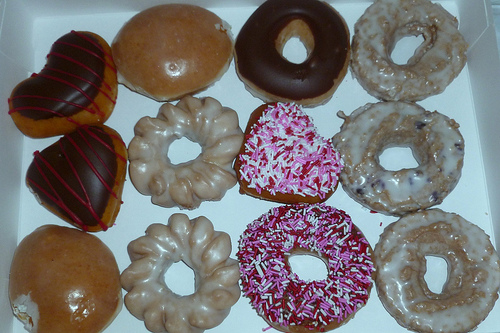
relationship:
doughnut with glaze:
[22, 119, 136, 234] [22, 127, 112, 227]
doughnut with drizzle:
[22, 119, 136, 234] [24, 129, 131, 225]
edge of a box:
[0, 5, 27, 322] [8, 5, 476, 328]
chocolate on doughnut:
[231, 1, 353, 104] [232, 1, 349, 106]